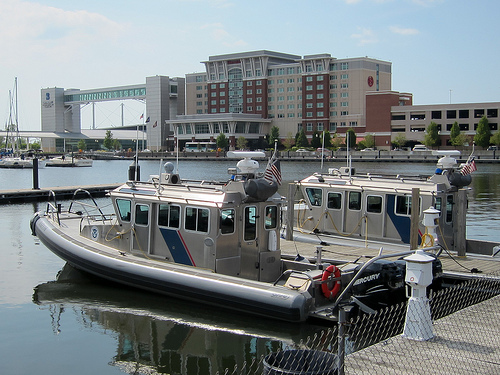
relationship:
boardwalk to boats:
[306, 228, 428, 283] [38, 98, 480, 330]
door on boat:
[131, 198, 153, 255] [30, 125, 444, 323]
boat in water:
[30, 125, 444, 323] [0, 160, 498, 374]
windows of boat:
[116, 193, 132, 225] [28, 160, 445, 317]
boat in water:
[28, 160, 445, 317] [0, 153, 463, 373]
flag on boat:
[258, 148, 288, 189] [30, 125, 444, 323]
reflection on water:
[36, 267, 290, 372] [2, 322, 331, 367]